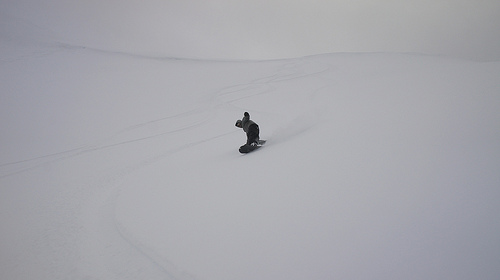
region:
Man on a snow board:
[225, 88, 283, 160]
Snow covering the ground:
[40, 225, 70, 260]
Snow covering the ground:
[77, 226, 130, 273]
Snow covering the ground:
[145, 234, 191, 279]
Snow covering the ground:
[205, 204, 275, 243]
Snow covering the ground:
[300, 241, 338, 272]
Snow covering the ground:
[333, 189, 378, 231]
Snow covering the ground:
[437, 237, 479, 277]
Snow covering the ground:
[345, 83, 415, 128]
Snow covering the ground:
[258, 71, 335, 103]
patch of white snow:
[332, 176, 360, 211]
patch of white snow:
[202, 243, 243, 279]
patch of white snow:
[376, 207, 399, 233]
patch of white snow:
[117, 213, 142, 240]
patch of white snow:
[372, 153, 407, 190]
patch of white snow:
[311, 170, 350, 202]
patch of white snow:
[113, 178, 146, 210]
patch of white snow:
[344, 126, 385, 165]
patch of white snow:
[334, 104, 381, 147]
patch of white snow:
[101, 159, 130, 194]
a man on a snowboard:
[231, 111, 264, 152]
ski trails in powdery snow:
[0, 97, 208, 279]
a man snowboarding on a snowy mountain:
[2, 93, 297, 278]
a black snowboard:
[237, 140, 263, 153]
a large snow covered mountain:
[0, 3, 498, 275]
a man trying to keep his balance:
[233, 105, 267, 160]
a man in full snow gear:
[228, 110, 269, 159]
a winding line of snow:
[45, 32, 491, 67]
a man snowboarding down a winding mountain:
[0, 104, 283, 274]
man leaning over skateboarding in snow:
[232, 108, 260, 142]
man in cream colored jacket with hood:
[233, 110, 253, 132]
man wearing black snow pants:
[246, 126, 261, 141]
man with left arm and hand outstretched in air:
[236, 109, 265, 145]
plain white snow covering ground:
[9, 0, 499, 272]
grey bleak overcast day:
[13, 0, 499, 266]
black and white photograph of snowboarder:
[3, 0, 498, 273]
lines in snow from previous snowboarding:
[28, 53, 346, 278]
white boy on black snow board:
[228, 111, 265, 153]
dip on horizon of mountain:
[4, 29, 495, 87]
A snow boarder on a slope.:
[217, 90, 278, 159]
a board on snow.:
[234, 139, 272, 154]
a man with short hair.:
[227, 109, 246, 136]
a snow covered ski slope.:
[338, 128, 435, 210]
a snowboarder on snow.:
[229, 100, 276, 157]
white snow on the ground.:
[284, 169, 346, 213]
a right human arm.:
[241, 105, 255, 125]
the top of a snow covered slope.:
[1, 22, 492, 66]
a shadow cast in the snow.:
[257, 115, 321, 154]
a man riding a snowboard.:
[219, 100, 273, 167]